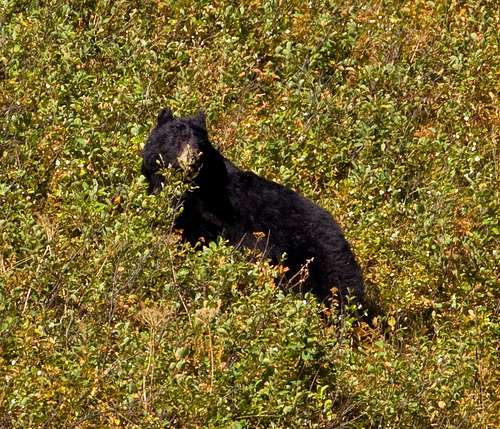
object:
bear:
[141, 106, 370, 322]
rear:
[323, 212, 367, 310]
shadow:
[175, 151, 234, 242]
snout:
[188, 155, 203, 172]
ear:
[157, 106, 174, 127]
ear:
[192, 110, 205, 128]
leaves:
[1, 1, 499, 429]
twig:
[284, 256, 313, 290]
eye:
[179, 135, 188, 146]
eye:
[200, 141, 206, 152]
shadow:
[362, 288, 422, 359]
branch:
[152, 146, 201, 213]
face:
[147, 122, 206, 178]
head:
[143, 107, 208, 192]